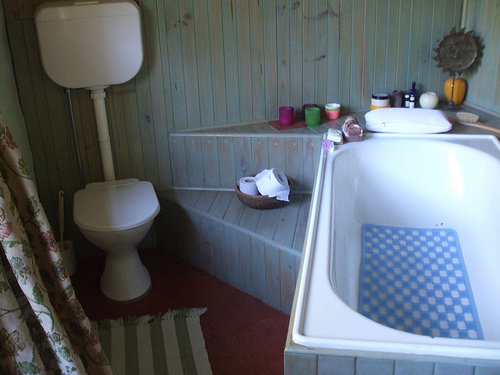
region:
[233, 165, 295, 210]
Rolls of toilet paper in brown bowl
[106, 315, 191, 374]
Green and white striped rug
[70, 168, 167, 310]
White toilet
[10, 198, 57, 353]
Flower patterned curtain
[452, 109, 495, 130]
Brown scrub brush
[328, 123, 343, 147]
Bar of soap on edge of tub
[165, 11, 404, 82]
Wood paneling wall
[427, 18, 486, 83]
Decorative metal sub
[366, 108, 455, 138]
White pillow next to tub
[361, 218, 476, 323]
Blue no-slip mat on bottom of tub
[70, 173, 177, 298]
white toilet bowl in a bathroom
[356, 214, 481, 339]
safety mat in a tub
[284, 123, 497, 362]
white tub in a bathroom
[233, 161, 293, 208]
toilet paper in a basket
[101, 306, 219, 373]
striped mat on the floor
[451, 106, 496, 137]
back brush by tub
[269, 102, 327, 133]
candles on a shelf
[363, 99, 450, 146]
pillow by a bathtub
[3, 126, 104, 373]
curtains in a bathroom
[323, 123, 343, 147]
soap by a bathtub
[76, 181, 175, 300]
A white toilet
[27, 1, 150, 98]
the water basin for the toilet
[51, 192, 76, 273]
A white toilet brush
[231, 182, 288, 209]
a wicker basket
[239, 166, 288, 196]
two rolls of toilet paper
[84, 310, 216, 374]
A green and white rug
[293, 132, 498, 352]
A white bath tub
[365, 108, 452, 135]
A white pillow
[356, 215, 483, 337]
A blue anti-slick bath mat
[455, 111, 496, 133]
A wooden brush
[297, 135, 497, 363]
A bath tub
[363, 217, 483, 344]
A blue anti-slick mat in the tub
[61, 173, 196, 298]
A toilet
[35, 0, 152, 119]
The water basin for the toilet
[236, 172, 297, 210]
A wicker basket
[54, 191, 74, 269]
A toilet brush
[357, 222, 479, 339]
a blue and white bathmat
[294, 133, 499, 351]
a large white tub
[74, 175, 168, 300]
a white toilet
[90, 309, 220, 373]
part of a green and white area rug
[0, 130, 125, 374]
part of a curtain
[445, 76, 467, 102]
a yellow vase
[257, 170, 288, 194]
a roll of tissue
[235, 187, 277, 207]
a brown basket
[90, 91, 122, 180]
a long white pole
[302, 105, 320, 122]
a small green cup